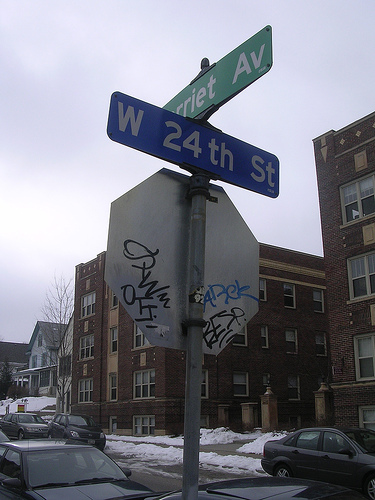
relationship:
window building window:
[341, 187, 371, 255] [320, 432, 348, 453]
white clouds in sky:
[12, 14, 190, 92] [23, 92, 78, 160]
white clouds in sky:
[12, 14, 190, 92] [18, 78, 81, 169]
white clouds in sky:
[12, 14, 190, 92] [36, 114, 94, 175]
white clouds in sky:
[12, 14, 190, 92] [11, 116, 74, 185]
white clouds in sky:
[12, 14, 190, 92] [25, 99, 90, 229]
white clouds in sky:
[12, 14, 190, 92] [306, 40, 359, 87]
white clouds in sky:
[12, 14, 190, 92] [70, 39, 149, 75]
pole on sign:
[184, 196, 208, 495] [103, 166, 272, 350]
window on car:
[320, 432, 348, 453] [273, 408, 359, 470]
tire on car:
[272, 465, 295, 481] [250, 430, 341, 480]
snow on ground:
[107, 437, 256, 475] [117, 429, 246, 489]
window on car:
[320, 432, 348, 453] [264, 421, 363, 499]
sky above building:
[3, 3, 374, 122] [82, 197, 310, 455]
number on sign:
[163, 118, 205, 161] [138, 106, 240, 190]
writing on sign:
[106, 236, 265, 352] [104, 213, 265, 366]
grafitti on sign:
[114, 238, 257, 348] [109, 226, 278, 374]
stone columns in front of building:
[303, 386, 339, 423] [54, 107, 373, 472]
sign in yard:
[12, 398, 35, 415] [10, 389, 59, 416]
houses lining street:
[0, 317, 77, 429] [5, 408, 298, 497]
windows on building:
[72, 282, 111, 421] [301, 112, 374, 445]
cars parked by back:
[6, 401, 104, 447] [102, 172, 263, 350]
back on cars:
[102, 172, 263, 350] [6, 401, 104, 447]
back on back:
[102, 172, 263, 350] [102, 172, 263, 350]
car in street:
[245, 415, 372, 491] [4, 413, 331, 498]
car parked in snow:
[245, 415, 372, 491] [97, 422, 287, 473]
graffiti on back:
[110, 243, 267, 357] [102, 172, 263, 350]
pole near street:
[174, 196, 227, 499] [24, 409, 276, 490]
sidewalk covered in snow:
[102, 427, 265, 465] [95, 410, 293, 476]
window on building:
[320, 432, 348, 453] [60, 237, 331, 427]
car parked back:
[245, 415, 372, 491] [102, 172, 263, 350]